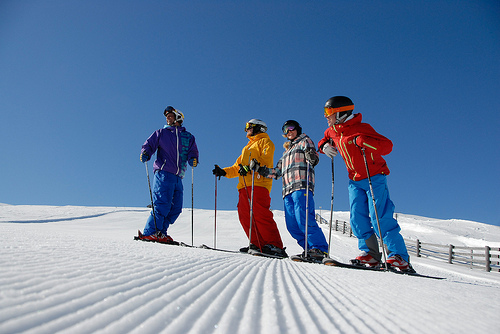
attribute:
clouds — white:
[63, 0, 470, 87]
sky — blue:
[51, 11, 500, 94]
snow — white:
[35, 207, 94, 248]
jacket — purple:
[141, 125, 204, 176]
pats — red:
[235, 186, 281, 261]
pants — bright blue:
[334, 179, 412, 265]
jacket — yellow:
[224, 139, 272, 189]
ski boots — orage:
[237, 241, 285, 257]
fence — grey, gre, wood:
[427, 244, 500, 264]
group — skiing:
[133, 89, 426, 272]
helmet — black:
[324, 95, 357, 124]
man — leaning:
[318, 85, 412, 277]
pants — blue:
[135, 166, 189, 239]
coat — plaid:
[269, 144, 317, 198]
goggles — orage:
[320, 105, 356, 115]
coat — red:
[318, 127, 397, 177]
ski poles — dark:
[184, 166, 197, 250]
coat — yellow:
[215, 131, 279, 194]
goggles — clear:
[281, 125, 302, 135]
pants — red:
[224, 188, 279, 254]